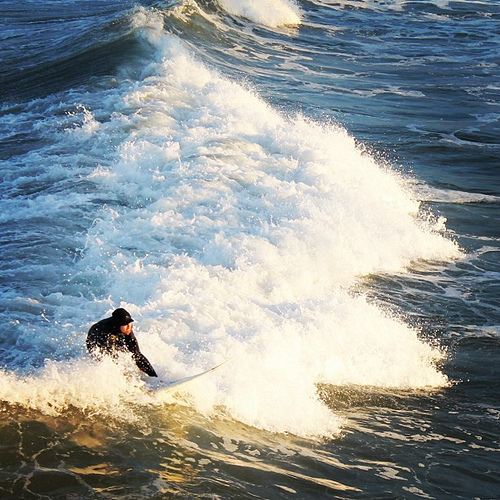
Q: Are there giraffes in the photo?
A: Yes, there is a giraffe.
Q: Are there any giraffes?
A: Yes, there is a giraffe.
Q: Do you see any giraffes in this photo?
A: Yes, there is a giraffe.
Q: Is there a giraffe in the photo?
A: Yes, there is a giraffe.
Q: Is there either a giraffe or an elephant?
A: Yes, there is a giraffe.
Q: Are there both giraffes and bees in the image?
A: No, there is a giraffe but no bees.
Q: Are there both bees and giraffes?
A: No, there is a giraffe but no bees.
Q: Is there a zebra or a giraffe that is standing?
A: Yes, the giraffe is standing.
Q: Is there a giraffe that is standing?
A: Yes, there is a giraffe that is standing.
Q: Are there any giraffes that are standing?
A: Yes, there is a giraffe that is standing.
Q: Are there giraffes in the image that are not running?
A: Yes, there is a giraffe that is standing.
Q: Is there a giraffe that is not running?
A: Yes, there is a giraffe that is standing.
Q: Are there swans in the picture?
A: No, there are no swans.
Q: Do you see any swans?
A: No, there are no swans.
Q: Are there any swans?
A: No, there are no swans.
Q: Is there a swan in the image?
A: No, there are no swans.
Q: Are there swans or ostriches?
A: No, there are no swans or ostriches.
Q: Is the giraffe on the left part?
A: Yes, the giraffe is on the left of the image.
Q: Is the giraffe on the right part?
A: No, the giraffe is on the left of the image.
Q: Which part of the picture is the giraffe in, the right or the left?
A: The giraffe is on the left of the image.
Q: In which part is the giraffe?
A: The giraffe is on the left of the image.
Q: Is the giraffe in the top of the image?
A: Yes, the giraffe is in the top of the image.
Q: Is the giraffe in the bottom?
A: No, the giraffe is in the top of the image.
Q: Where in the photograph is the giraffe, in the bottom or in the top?
A: The giraffe is in the top of the image.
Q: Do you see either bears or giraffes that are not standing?
A: No, there is a giraffe but it is standing.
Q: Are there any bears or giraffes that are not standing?
A: No, there is a giraffe but it is standing.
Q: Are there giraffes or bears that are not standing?
A: No, there is a giraffe but it is standing.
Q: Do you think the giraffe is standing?
A: Yes, the giraffe is standing.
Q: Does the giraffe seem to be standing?
A: Yes, the giraffe is standing.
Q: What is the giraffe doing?
A: The giraffe is standing.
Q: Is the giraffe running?
A: No, the giraffe is standing.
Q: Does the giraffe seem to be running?
A: No, the giraffe is standing.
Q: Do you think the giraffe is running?
A: No, the giraffe is standing.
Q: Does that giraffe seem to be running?
A: No, the giraffe is standing.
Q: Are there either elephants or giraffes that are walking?
A: No, there is a giraffe but it is standing.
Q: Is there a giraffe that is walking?
A: No, there is a giraffe but it is standing.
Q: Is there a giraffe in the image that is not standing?
A: No, there is a giraffe but it is standing.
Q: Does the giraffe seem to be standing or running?
A: The giraffe is standing.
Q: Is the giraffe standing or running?
A: The giraffe is standing.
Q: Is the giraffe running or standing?
A: The giraffe is standing.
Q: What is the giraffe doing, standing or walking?
A: The giraffe is standing.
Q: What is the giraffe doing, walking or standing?
A: The giraffe is standing.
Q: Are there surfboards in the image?
A: Yes, there is a surfboard.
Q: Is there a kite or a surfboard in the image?
A: Yes, there is a surfboard.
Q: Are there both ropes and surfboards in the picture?
A: No, there is a surfboard but no ropes.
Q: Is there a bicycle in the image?
A: No, there are no bicycles.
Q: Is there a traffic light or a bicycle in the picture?
A: No, there are no bicycles or traffic lights.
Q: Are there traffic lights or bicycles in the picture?
A: No, there are no bicycles or traffic lights.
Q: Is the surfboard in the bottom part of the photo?
A: Yes, the surfboard is in the bottom of the image.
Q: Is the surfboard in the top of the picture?
A: No, the surfboard is in the bottom of the image.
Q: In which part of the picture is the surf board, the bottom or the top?
A: The surf board is in the bottom of the image.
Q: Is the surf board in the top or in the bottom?
A: The surf board is in the bottom of the image.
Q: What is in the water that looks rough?
A: The surf board is in the water.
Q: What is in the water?
A: The surf board is in the water.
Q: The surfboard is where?
A: The surfboard is in the water.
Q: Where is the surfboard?
A: The surfboard is in the water.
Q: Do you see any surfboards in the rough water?
A: Yes, there is a surfboard in the water.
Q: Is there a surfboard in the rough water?
A: Yes, there is a surfboard in the water.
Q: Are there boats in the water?
A: No, there is a surfboard in the water.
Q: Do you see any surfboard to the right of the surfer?
A: Yes, there is a surfboard to the right of the surfer.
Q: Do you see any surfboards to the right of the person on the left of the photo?
A: Yes, there is a surfboard to the right of the surfer.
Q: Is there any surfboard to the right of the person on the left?
A: Yes, there is a surfboard to the right of the surfer.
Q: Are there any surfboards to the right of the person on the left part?
A: Yes, there is a surfboard to the right of the surfer.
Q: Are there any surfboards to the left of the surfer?
A: No, the surfboard is to the right of the surfer.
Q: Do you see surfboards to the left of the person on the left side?
A: No, the surfboard is to the right of the surfer.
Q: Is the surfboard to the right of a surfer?
A: Yes, the surfboard is to the right of a surfer.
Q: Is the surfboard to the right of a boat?
A: No, the surfboard is to the right of a surfer.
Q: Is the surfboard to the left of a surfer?
A: No, the surfboard is to the right of a surfer.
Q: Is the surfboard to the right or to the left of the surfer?
A: The surfboard is to the right of the surfer.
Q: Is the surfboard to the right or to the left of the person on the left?
A: The surfboard is to the right of the surfer.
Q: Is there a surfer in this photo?
A: Yes, there is a surfer.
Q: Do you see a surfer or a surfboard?
A: Yes, there is a surfer.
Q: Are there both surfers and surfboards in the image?
A: Yes, there are both a surfer and a surfboard.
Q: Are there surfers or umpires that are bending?
A: Yes, the surfer is bending.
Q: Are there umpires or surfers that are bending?
A: Yes, the surfer is bending.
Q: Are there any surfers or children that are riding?
A: Yes, the surfer is riding.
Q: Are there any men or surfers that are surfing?
A: Yes, the surfer is surfing.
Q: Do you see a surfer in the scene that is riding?
A: Yes, there is a surfer that is riding.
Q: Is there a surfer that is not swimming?
A: Yes, there is a surfer that is riding.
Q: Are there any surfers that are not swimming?
A: Yes, there is a surfer that is riding.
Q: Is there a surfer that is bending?
A: Yes, there is a surfer that is bending.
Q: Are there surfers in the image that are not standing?
A: Yes, there is a surfer that is bending.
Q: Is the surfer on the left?
A: Yes, the surfer is on the left of the image.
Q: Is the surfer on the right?
A: No, the surfer is on the left of the image.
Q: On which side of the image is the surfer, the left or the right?
A: The surfer is on the left of the image.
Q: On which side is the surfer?
A: The surfer is on the left of the image.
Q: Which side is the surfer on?
A: The surfer is on the left of the image.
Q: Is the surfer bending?
A: Yes, the surfer is bending.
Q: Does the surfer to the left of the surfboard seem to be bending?
A: Yes, the surfer is bending.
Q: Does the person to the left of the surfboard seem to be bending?
A: Yes, the surfer is bending.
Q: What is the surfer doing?
A: The surfer is bending.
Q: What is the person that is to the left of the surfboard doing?
A: The surfer is bending.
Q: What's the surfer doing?
A: The surfer is bending.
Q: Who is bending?
A: The surfer is bending.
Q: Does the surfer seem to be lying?
A: No, the surfer is bending.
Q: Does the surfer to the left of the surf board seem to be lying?
A: No, the surfer is bending.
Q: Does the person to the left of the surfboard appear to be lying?
A: No, the surfer is bending.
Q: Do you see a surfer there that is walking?
A: No, there is a surfer but he is bending.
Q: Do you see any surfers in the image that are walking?
A: No, there is a surfer but he is bending.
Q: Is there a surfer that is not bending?
A: No, there is a surfer but he is bending.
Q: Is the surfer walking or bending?
A: The surfer is bending.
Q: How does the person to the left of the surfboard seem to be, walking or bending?
A: The surfer is bending.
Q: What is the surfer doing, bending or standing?
A: The surfer is bending.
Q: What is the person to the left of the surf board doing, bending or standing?
A: The surfer is bending.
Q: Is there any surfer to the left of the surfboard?
A: Yes, there is a surfer to the left of the surfboard.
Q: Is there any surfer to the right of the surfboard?
A: No, the surfer is to the left of the surfboard.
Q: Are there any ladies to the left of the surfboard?
A: No, there is a surfer to the left of the surfboard.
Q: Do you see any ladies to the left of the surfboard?
A: No, there is a surfer to the left of the surfboard.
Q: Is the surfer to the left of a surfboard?
A: Yes, the surfer is to the left of a surfboard.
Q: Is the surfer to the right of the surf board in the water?
A: No, the surfer is to the left of the surfboard.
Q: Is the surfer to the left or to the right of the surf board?
A: The surfer is to the left of the surf board.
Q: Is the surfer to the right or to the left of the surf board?
A: The surfer is to the left of the surf board.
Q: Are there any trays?
A: No, there are no trays.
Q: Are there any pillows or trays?
A: No, there are no trays or pillows.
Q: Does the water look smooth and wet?
A: No, the water is wet but rough.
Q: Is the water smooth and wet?
A: No, the water is wet but rough.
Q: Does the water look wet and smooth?
A: No, the water is wet but rough.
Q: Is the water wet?
A: Yes, the water is wet.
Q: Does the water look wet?
A: Yes, the water is wet.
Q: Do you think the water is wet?
A: Yes, the water is wet.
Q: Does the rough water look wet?
A: Yes, the water is wet.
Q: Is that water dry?
A: No, the water is wet.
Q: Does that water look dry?
A: No, the water is wet.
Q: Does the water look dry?
A: No, the water is wet.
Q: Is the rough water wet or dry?
A: The water is wet.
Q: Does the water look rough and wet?
A: Yes, the water is rough and wet.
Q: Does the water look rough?
A: Yes, the water is rough.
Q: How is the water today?
A: The water is rough.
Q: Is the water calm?
A: No, the water is rough.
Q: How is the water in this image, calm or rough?
A: The water is rough.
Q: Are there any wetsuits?
A: Yes, there is a wetsuit.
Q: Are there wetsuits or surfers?
A: Yes, there is a wetsuit.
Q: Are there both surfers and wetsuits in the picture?
A: Yes, there are both a wetsuit and a surfer.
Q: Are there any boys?
A: No, there are no boys.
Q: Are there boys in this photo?
A: No, there are no boys.